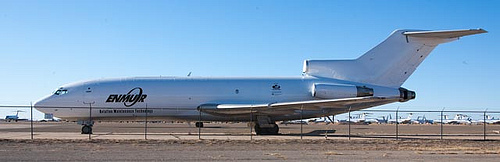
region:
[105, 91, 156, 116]
Black logo on the side of a plane.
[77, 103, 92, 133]
Black logo on the side of a plane.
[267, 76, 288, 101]
Black logo on the side of a plane.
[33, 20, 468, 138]
a white plane parked on the tarmac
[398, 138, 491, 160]
dead brown grass on the ground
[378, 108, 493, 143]
grey metal chain link fence of the airport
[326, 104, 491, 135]
several planes parked at the terminal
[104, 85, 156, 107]
black logo on the side of the plane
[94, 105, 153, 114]
black lettering on the side of the plane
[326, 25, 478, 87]
white tail fin of the plane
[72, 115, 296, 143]
landing gear of the plane on the ground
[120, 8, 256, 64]
clear blue skies over the airport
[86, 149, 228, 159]
black asphalt surface of the road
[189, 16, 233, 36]
this is the sky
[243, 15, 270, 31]
the sky is blue in color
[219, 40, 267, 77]
the sky has clouds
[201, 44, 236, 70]
the clouds are white in color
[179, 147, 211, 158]
this is the ground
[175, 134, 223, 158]
the ground is sandy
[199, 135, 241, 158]
the sand is brown in color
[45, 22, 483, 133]
this is an airplane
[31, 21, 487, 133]
the airplane is big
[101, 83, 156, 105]
these are some writings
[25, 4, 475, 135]
this is a plane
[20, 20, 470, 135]
the plane is on the ground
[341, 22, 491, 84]
this is the tail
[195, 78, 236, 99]
the plane is white in color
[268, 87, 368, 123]
this is the wing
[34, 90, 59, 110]
this is the front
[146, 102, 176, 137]
this is the fence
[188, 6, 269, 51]
this is the sky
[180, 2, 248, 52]
the sky is clear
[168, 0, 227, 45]
the sky is blue in color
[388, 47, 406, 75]
edge of a wing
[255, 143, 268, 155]
part of a ground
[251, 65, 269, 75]
edge of a plane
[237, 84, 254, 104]
part of a plane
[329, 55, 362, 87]
part of a plane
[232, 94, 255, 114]
part of a fence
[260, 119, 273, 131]
part of a wheel